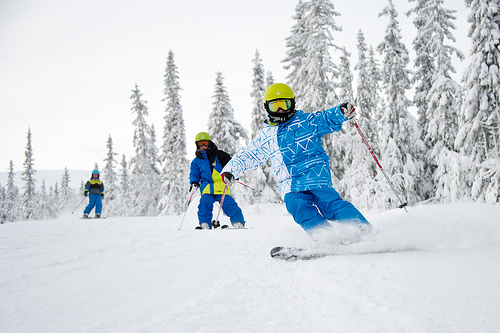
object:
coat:
[221, 102, 351, 193]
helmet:
[264, 83, 295, 99]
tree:
[129, 83, 159, 218]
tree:
[162, 50, 187, 216]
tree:
[282, 2, 348, 199]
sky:
[1, 1, 126, 127]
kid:
[221, 83, 364, 248]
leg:
[313, 188, 368, 232]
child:
[190, 132, 242, 230]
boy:
[84, 168, 105, 219]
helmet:
[195, 132, 210, 141]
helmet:
[92, 169, 99, 174]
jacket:
[189, 145, 232, 195]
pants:
[283, 189, 366, 238]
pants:
[197, 194, 241, 227]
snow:
[1, 200, 498, 326]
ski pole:
[352, 116, 408, 214]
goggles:
[267, 99, 293, 113]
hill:
[2, 169, 131, 196]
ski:
[271, 247, 420, 260]